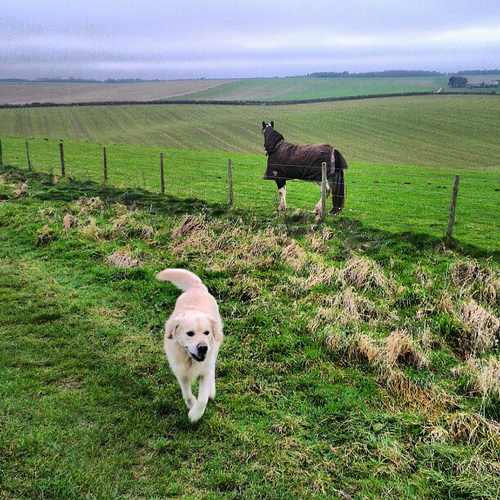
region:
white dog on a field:
[151, 264, 223, 424]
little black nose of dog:
[198, 342, 207, 353]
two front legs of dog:
[176, 373, 211, 429]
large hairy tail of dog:
[151, 267, 206, 284]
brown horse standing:
[256, 118, 346, 215]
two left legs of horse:
[273, 184, 329, 213]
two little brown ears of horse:
[258, 115, 275, 126]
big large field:
[1, 77, 498, 499]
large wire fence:
[6, 137, 491, 265]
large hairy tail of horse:
[334, 150, 348, 194]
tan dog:
[148, 255, 239, 437]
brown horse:
[246, 102, 367, 225]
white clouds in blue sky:
[35, 7, 54, 49]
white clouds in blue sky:
[85, 7, 133, 58]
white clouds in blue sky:
[23, 18, 53, 48]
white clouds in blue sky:
[101, 9, 154, 60]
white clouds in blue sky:
[233, 14, 263, 62]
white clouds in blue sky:
[132, 27, 178, 60]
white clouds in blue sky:
[326, 16, 361, 44]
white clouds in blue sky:
[366, 25, 410, 57]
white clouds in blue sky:
[6, 25, 56, 56]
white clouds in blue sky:
[48, 7, 106, 60]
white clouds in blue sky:
[130, 14, 193, 49]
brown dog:
[122, 264, 244, 439]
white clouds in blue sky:
[117, 4, 161, 72]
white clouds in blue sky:
[221, 22, 288, 94]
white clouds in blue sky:
[282, 20, 339, 65]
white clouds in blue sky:
[429, 13, 490, 67]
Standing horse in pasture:
[253, 117, 356, 220]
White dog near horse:
[145, 267, 249, 426]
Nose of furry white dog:
[190, 343, 206, 352]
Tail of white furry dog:
[153, 262, 205, 292]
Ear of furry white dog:
[160, 314, 187, 336]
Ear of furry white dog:
[205, 317, 226, 339]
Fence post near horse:
[154, 155, 170, 202]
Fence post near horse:
[221, 154, 239, 205]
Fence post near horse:
[445, 167, 462, 240]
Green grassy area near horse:
[372, 184, 435, 209]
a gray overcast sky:
[20, 9, 478, 76]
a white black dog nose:
[194, 341, 211, 351]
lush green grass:
[14, 374, 134, 476]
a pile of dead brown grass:
[344, 288, 369, 322]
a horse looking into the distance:
[257, 108, 372, 221]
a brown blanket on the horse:
[276, 145, 328, 172]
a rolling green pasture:
[386, 95, 496, 167]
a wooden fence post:
[444, 174, 460, 242]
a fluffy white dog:
[155, 264, 219, 409]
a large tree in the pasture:
[441, 69, 471, 90]